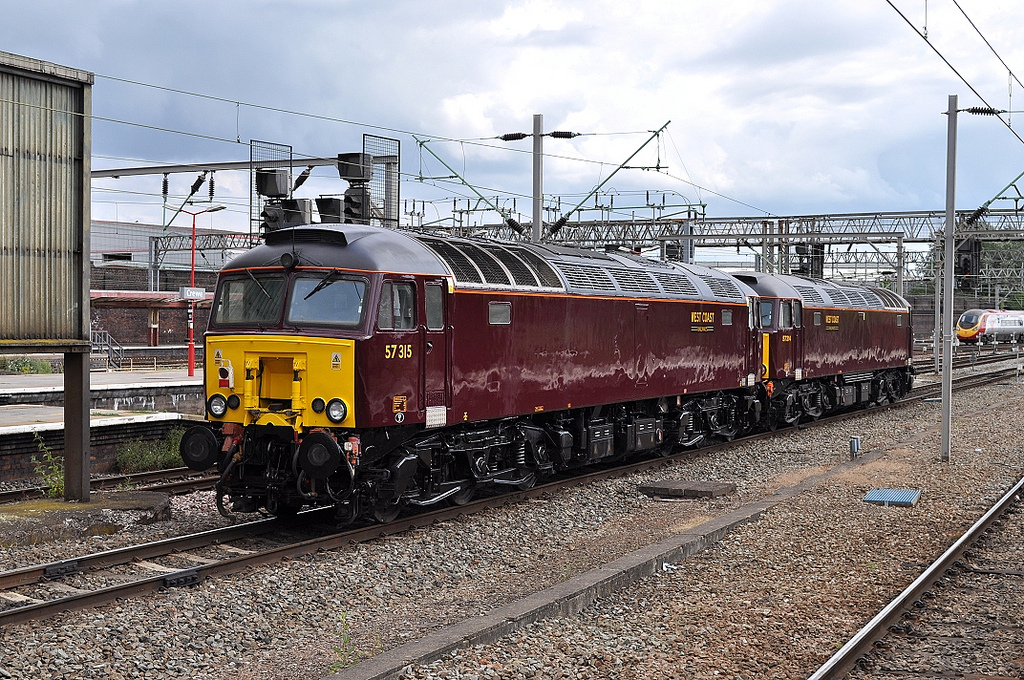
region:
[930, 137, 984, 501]
pole beside the tracks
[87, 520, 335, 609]
the tracks are steel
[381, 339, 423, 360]
numbers on the train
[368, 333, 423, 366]
the numbers are golden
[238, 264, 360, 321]
wipers on the window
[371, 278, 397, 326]
red train has a window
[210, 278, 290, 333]
red train has a window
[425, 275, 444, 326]
red train has a window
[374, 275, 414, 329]
red train has a window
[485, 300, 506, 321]
red train has a window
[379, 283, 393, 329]
red train has a window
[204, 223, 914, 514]
A brown and yellow locomotive.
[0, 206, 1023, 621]
A double engine locomotive on tracks.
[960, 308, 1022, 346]
A passenger train in the background.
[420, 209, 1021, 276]
The high rising metallic bridge.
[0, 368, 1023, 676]
The gravel filled grounds.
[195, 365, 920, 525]
The dark colored bogie.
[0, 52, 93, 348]
The billboard on the left.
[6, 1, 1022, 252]
A sparsely clouded blue sky.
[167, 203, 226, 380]
The red beam outdoor lighting.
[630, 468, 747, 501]
Slab of wood on top of the rocks.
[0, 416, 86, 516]
Small tree on the side of the building.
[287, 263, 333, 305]
Black wind shield wiper going across the glass.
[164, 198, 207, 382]
Long orange pole by the buildings.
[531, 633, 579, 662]
Bunch of gravel and rocks on the side of train.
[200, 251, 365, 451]
front of a train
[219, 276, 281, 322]
window of a train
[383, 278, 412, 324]
window of a train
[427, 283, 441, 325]
window of a train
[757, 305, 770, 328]
window of a train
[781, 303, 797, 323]
window of a train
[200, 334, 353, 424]
the paint is yellow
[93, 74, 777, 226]
wires in the air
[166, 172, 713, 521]
this is a train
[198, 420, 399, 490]
the bumper is black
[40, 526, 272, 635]
the rails are brown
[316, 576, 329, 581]
A rock on the ground.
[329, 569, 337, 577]
A rock on the ground.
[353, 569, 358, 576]
A rock on the ground.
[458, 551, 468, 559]
A rock on the ground.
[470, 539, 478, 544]
A rock on the ground.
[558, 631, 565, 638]
A rock on the ground.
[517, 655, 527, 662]
A rock on the ground.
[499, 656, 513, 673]
A rock on the ground.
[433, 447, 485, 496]
A tire on a vehicle.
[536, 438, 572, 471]
A tire on a vehicle.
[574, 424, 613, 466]
A tire on a vehicle.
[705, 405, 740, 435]
A tire on a vehicle.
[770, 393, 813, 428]
A tire on a vehicle.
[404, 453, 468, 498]
A wheel on a train.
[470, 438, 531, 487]
A wheel on a train.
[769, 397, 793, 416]
A wheel on a train.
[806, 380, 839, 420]
A wheel on a train.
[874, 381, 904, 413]
A wheel on a train.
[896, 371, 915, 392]
A wheel on a train.